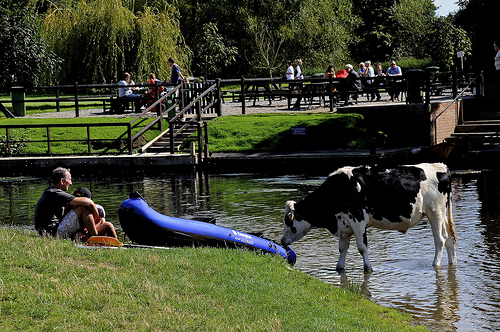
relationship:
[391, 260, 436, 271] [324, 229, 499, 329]
reflection in water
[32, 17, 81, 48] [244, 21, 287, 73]
leaves on trees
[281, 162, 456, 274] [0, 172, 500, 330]
cow in water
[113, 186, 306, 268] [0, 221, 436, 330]
raft on grass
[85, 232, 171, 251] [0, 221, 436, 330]
oar on grass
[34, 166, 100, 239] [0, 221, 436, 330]
man on grass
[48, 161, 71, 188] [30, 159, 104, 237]
head on man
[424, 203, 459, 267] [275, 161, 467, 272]
legs on cow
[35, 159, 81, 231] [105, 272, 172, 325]
man sitting grass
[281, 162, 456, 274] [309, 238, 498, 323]
cow standing water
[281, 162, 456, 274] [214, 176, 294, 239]
cow standing water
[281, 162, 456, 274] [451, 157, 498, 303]
cow standing water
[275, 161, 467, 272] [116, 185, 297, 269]
cow smelling canoe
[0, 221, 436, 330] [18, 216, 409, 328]
grass on ground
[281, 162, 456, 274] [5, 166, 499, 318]
cow in water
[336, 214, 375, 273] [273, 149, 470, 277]
legs on cow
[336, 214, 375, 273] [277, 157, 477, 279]
legs on cow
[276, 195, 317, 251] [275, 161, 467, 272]
head on cow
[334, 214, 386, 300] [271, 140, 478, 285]
legs on cow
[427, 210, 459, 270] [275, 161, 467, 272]
legs on cow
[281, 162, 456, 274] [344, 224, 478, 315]
cow in water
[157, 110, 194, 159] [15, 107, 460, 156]
steps down hill